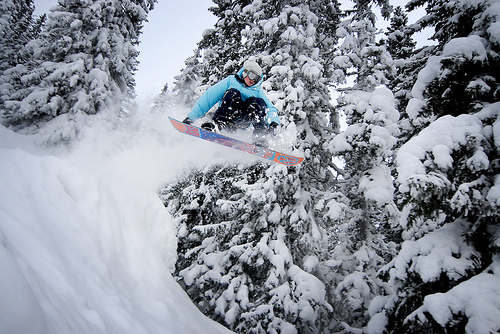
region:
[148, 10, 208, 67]
light blue daytime sky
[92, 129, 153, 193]
snow being kicked up by snowboarder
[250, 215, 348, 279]
snow on evergreen trees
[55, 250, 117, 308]
steep snow covered hill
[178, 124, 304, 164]
colorful designs on bottom of snowboard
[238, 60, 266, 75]
white hat on snowboarder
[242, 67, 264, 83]
goggles on person's face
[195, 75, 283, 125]
light blue winter jacket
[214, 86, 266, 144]
black pants on snowboarder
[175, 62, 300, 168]
snowboarder in the air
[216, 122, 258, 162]
part of a skating board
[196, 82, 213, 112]
part of a blue jacket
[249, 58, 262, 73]
part of a white marvin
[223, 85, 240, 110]
part of a right knee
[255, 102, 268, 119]
part of a left knee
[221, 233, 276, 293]
part of some tree branches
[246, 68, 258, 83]
part of sun glasses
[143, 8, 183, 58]
part of the sky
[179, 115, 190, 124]
part of the right hand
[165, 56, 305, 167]
a boy snowboarding on a slope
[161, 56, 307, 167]
a snowboarder getting air on his board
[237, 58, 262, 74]
the boy has a knit hat on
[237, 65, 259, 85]
he is wearing snow goggles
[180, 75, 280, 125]
he has a blue down ski jacket on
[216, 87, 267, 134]
the snowboarder has black ski pants on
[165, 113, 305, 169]
the snowboard is orange and blue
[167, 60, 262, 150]
the snowboarder has a hand on the back of the board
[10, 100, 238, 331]
the steep slope is covered with powder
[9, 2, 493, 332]
the trees are blanketed with snow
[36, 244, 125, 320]
part of some snow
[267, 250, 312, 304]
part of some branches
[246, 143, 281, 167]
part of skating board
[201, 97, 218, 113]
part of a blue jacket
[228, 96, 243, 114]
part of a black track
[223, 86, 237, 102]
part of the right knee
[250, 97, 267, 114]
part of the left knee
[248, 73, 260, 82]
part of some sunglasses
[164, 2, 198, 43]
part of the sky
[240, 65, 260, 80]
goggles on person's eyes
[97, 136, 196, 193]
snow kicked up by snowboard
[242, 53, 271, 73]
hat on snowboarder's head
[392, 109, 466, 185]
snow on evergreen tree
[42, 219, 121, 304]
steep hill of snow